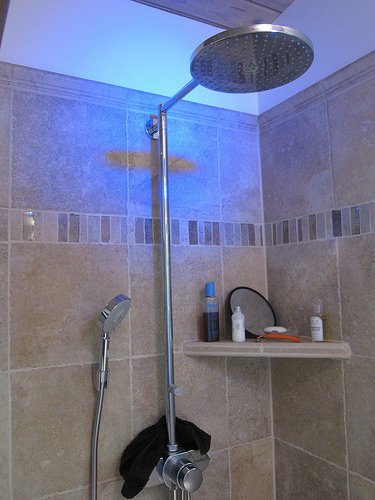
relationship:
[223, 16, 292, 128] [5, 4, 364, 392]
corner of shower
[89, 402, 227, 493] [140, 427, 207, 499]
washcloth on handle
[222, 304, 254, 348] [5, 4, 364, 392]
soap in shower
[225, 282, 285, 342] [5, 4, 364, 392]
mirror in shower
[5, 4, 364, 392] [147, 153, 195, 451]
shower water pipes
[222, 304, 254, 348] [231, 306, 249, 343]
soap in bottle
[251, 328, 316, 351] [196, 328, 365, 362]
razor on shelf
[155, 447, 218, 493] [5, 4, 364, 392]
knob in shower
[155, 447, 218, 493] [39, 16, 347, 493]
knob for water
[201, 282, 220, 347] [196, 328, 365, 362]
bottle on shelf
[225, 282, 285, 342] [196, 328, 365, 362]
mirror on shelf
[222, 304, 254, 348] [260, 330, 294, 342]
soap in dish